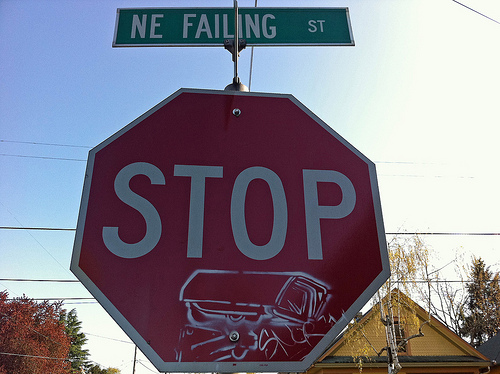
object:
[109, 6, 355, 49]
street name sign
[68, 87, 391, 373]
stop sign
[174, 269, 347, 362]
graffiti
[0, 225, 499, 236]
electrical wire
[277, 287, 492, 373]
home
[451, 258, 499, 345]
trees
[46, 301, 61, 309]
leaves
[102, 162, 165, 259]
s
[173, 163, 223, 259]
t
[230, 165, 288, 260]
o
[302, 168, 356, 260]
p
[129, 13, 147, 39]
n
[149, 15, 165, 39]
e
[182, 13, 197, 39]
f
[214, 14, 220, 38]
i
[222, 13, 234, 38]
l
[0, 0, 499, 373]
sky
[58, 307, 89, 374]
tree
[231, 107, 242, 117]
screw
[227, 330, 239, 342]
bolt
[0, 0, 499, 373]
clear view